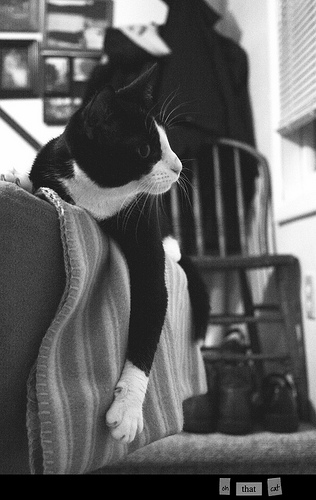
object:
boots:
[251, 371, 300, 435]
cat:
[28, 79, 212, 441]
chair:
[169, 139, 309, 425]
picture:
[43, 55, 100, 121]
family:
[0, 40, 31, 91]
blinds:
[274, 0, 315, 134]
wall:
[223, 1, 315, 425]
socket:
[302, 275, 316, 320]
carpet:
[89, 421, 316, 476]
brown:
[89, 422, 316, 475]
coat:
[154, 0, 260, 258]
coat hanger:
[151, 0, 221, 31]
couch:
[0, 177, 209, 478]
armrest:
[0, 175, 67, 480]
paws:
[106, 378, 144, 444]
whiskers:
[161, 98, 198, 127]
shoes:
[182, 369, 254, 435]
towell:
[25, 183, 209, 479]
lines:
[53, 195, 88, 475]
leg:
[158, 207, 181, 262]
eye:
[136, 142, 150, 157]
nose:
[171, 158, 183, 173]